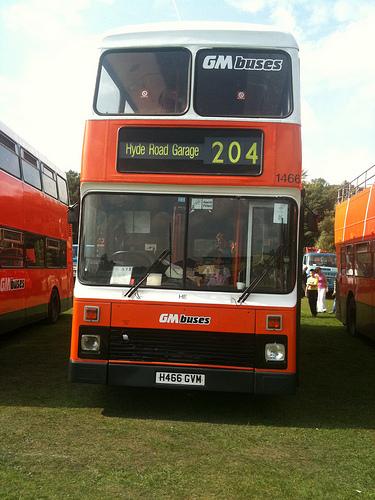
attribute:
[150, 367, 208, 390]
license plate — white, small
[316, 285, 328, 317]
skirt — white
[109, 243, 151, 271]
steering wheel — black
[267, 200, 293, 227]
paper — white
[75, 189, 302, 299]
windshield — dark, large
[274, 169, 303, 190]
1466 — bus id, number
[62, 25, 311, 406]
bus — double-decker, orange, gm buses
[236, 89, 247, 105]
sticker — red, white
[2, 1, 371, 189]
sky — blue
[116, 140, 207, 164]
hyde road garage — destination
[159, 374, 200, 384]
h466 gvm — license number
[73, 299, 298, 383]
bus front — orange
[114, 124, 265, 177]
display — for destination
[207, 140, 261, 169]
204 — number, bus number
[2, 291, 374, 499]
grass — green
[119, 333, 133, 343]
object — small, silver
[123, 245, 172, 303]
windshield wiper — long, black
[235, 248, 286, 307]
windshield wiper — black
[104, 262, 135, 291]
sign — white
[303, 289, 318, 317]
pants — black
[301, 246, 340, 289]
truck — blue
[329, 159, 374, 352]
bus — tourist bus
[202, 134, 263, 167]
number — 204